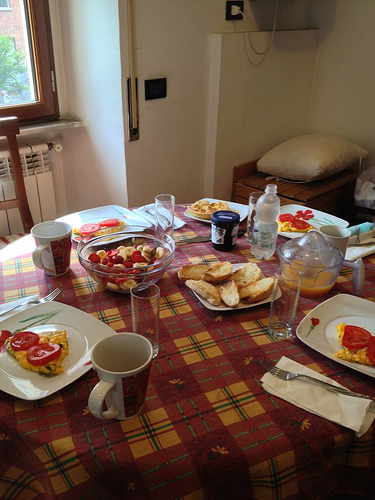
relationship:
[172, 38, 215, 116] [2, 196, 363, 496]
wall behind table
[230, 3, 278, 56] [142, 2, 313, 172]
white cord on wall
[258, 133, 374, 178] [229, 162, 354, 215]
tan pillow on table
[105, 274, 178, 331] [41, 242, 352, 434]
glass is on table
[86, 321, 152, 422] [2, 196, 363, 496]
mug is on table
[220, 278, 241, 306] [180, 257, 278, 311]
bread is on plate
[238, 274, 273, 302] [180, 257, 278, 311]
bread is on plate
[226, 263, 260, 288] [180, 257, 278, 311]
bread is on plate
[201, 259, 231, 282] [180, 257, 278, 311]
bread is on plate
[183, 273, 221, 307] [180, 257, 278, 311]
bread is on plate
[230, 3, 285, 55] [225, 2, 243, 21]
white cord is in outlet